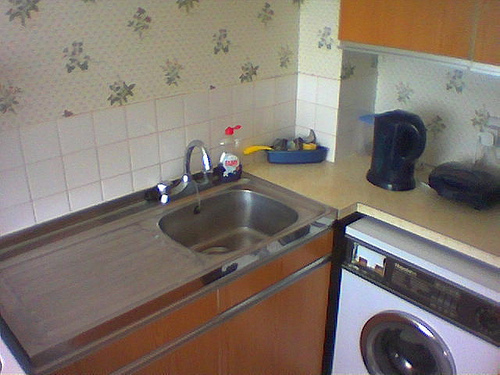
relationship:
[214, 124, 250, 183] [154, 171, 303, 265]
detergent on top of sink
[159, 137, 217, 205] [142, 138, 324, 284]
faucet over sink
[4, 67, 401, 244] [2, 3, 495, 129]
tile on a wall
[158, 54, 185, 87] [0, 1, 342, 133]
flower on a wallpaper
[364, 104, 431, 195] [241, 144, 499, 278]
tea kettle on a counter top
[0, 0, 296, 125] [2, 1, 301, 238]
wallpaper on a wall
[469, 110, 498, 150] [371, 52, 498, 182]
outlet on a wall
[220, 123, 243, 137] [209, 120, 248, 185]
cap on top of bottle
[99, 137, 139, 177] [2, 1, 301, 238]
tile on wall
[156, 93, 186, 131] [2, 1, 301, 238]
tile on wall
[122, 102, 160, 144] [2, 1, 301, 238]
tile on wall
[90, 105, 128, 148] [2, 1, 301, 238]
tile on wall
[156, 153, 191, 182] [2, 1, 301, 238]
tile on wall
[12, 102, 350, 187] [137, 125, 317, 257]
tile above kitchen sink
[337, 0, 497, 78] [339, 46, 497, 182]
cabinets on wall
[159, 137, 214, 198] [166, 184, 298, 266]
faucet on sink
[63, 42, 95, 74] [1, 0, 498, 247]
flower on wall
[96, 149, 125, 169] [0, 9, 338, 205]
tile on wall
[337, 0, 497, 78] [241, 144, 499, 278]
cabinets are above counter top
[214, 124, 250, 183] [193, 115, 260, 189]
detergent in bottle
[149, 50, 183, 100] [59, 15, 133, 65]
flower on wall.